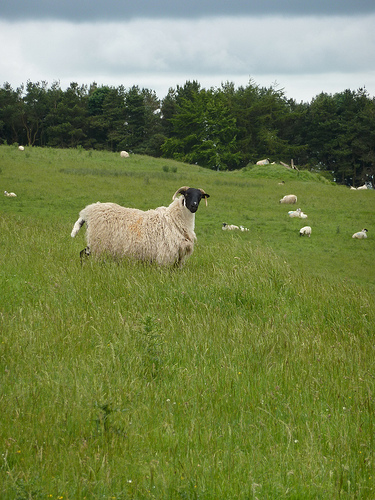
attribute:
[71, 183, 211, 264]
sheep — standing, fluffy, wooly, white, white brown black ta, old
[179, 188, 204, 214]
face — black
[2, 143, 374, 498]
grass — high, green, flowery, tall, weedy, hilly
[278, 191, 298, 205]
sheep — grazing, distant, eating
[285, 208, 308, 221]
sheep — grazing, distant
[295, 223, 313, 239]
sheep — grazing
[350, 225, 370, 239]
sheep — lying, looking away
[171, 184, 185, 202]
horn — turned down, long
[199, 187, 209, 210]
horn — turned down, long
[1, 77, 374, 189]
trees — green, tall, brown, dark green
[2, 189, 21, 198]
lamb — white, little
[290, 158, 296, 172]
post — old, wooden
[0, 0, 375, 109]
sky — blue, cloudy, white